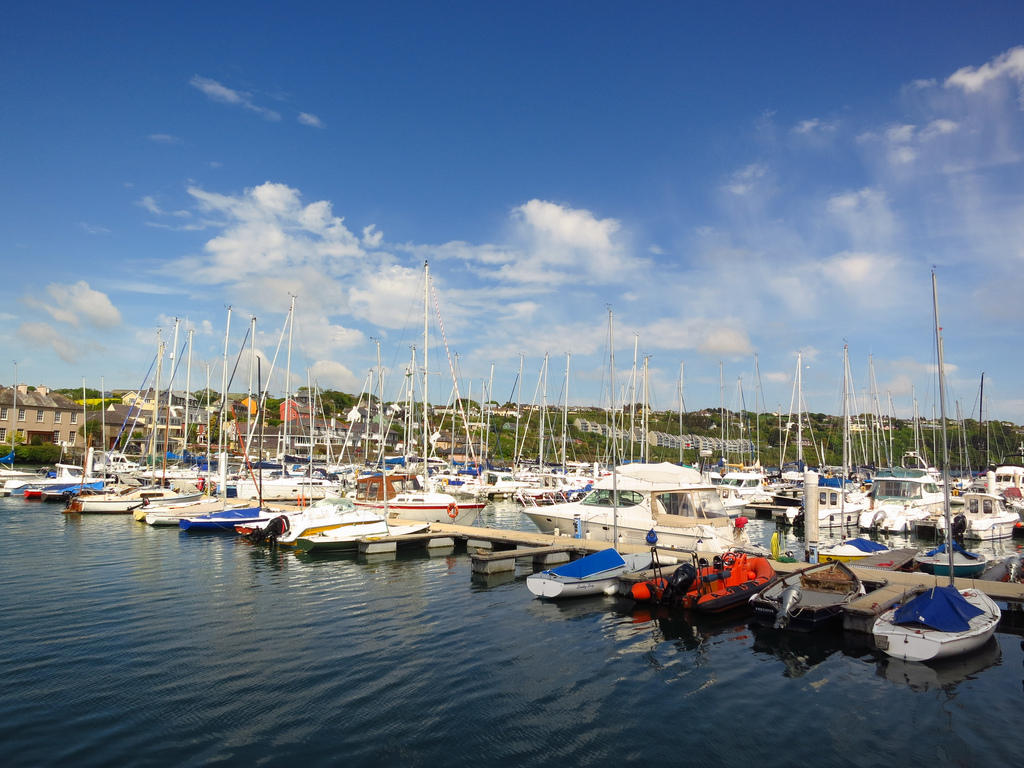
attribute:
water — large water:
[36, 525, 240, 765]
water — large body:
[55, 551, 313, 761]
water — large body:
[85, 573, 351, 759]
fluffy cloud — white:
[18, 16, 956, 315]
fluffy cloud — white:
[116, 158, 935, 312]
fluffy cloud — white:
[152, 178, 662, 323]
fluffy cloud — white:
[135, 150, 697, 321]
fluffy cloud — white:
[498, 191, 632, 310]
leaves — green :
[886, 420, 915, 434]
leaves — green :
[543, 407, 556, 418]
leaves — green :
[810, 418, 832, 440]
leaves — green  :
[880, 424, 919, 444]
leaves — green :
[657, 413, 738, 433]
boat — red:
[640, 541, 733, 617]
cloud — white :
[460, 217, 607, 293]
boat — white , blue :
[869, 573, 990, 660]